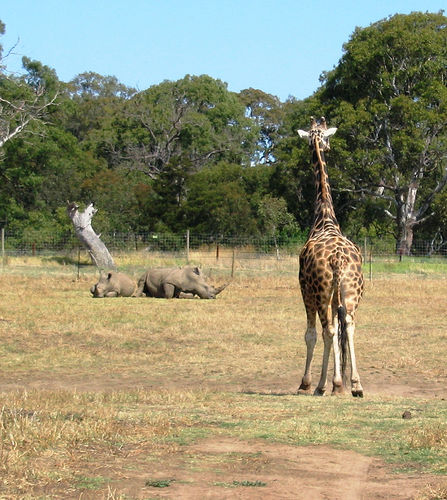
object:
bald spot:
[114, 439, 445, 499]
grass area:
[1, 266, 445, 498]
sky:
[0, 1, 445, 99]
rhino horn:
[91, 283, 99, 297]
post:
[2, 224, 11, 267]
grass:
[109, 327, 428, 459]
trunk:
[395, 184, 418, 255]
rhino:
[87, 264, 227, 304]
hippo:
[132, 265, 229, 299]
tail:
[330, 249, 352, 386]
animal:
[294, 115, 367, 396]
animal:
[134, 265, 229, 299]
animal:
[88, 271, 142, 298]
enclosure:
[109, 231, 300, 274]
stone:
[397, 399, 439, 429]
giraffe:
[288, 111, 376, 407]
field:
[5, 269, 437, 498]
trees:
[0, 56, 443, 248]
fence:
[1, 227, 445, 256]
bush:
[0, 218, 443, 253]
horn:
[212, 278, 233, 301]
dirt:
[31, 433, 446, 498]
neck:
[305, 144, 341, 231]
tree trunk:
[70, 209, 118, 280]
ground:
[5, 251, 434, 498]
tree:
[301, 12, 445, 252]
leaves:
[353, 41, 369, 60]